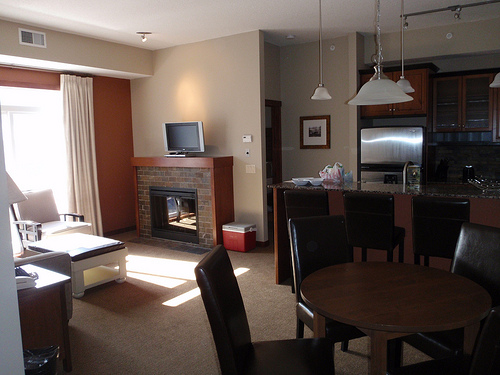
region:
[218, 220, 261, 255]
red and white icebox on a floor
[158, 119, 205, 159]
screen on a mantel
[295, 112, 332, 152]
art hanging on a wall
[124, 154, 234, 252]
wooden mantel and brick fireplace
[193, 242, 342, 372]
empty brown chair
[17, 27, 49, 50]
white vent on a wall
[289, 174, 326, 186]
white bowls on a counter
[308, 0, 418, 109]
three white lights hanging from a ceiling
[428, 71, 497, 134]
wood and glass kitchen cabinets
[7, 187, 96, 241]
white chair with a wooden frame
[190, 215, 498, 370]
A wooden table with black chairs.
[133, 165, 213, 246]
A brick fireplace.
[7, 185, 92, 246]
A white chair with wooden arm rests.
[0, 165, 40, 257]
A lamp with a white shade.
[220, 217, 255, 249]
A red and white cooler next to the fireplace.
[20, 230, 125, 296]
A brown and white coffee table.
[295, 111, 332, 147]
A framed picture hanging on a tan wall.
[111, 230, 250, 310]
Sunlight shining on the floor.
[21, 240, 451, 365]
A tan rug on the floor.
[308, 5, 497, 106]
Hanging lights with white covers.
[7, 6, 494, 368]
room with natural light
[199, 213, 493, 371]
chairs around round table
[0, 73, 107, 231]
white curtain next to window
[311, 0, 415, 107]
three lights hanging from cables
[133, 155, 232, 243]
fireplace with wood mantel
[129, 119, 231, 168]
flat screen television on mantel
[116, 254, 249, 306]
light reflection on carpet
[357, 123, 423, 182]
front of stainless steel refrigerator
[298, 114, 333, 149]
picture in mat and frame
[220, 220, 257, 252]
red cooler with white cover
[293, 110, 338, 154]
framed picture on wall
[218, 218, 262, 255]
red and white cooler on floor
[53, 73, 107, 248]
long white curtain panel on window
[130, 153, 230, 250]
brick face fireplace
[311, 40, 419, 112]
three white shade hanging ceiling lamps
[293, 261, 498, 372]
round wooden table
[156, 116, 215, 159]
silver and black television on fireplace mantle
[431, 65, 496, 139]
hanging wood cabinets with glass doors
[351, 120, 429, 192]
stainless steel refrigerator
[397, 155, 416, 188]
tall silver sink faucet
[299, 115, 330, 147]
Picture hanging on a wall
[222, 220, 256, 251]
A cooler that is red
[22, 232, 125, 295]
Coffee table in a room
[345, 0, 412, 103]
A light fixture hanging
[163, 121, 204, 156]
A TV set on a fireplace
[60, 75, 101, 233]
Curtains attached to a window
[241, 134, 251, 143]
The thermostat in a house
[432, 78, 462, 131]
A cabinet in a kitchen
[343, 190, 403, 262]
A lounge chair at the kitchen counter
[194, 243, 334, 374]
A black chair at a table